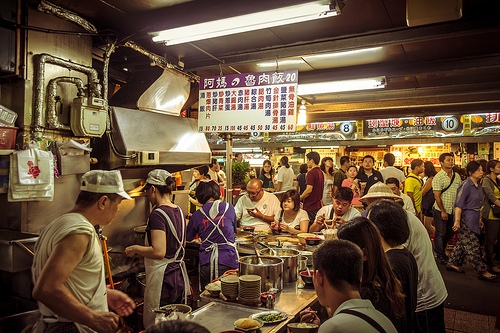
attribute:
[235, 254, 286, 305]
pot — metal, large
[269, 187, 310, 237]
woman — eating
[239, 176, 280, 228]
man — eating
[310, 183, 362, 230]
man — eating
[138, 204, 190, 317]
apron — white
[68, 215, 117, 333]
apron — white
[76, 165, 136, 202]
hat — white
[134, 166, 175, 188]
hat — white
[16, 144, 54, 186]
bag — white, red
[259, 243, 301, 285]
pot — stainless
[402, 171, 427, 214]
shirt — yellow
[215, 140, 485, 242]
people — crowd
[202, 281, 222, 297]
cap — white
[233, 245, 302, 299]
food — full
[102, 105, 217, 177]
hood fan — metal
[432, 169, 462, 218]
shirt — plaid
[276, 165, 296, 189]
shirt — white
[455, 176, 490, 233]
shirt — purple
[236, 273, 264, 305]
dishes — stack